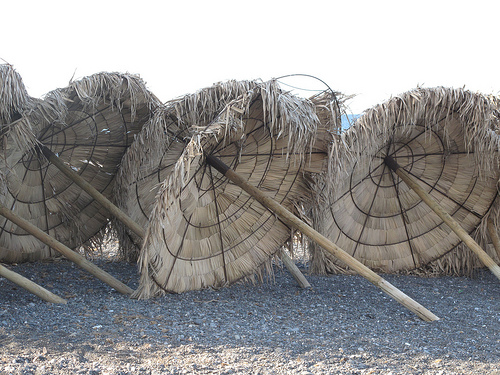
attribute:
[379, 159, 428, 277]
black support — on umbrella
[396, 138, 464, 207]
black support — on umbrella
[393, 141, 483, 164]
black support — on umbrella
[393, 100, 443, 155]
black support — on umbrella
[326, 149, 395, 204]
black support — on umbrella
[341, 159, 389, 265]
black support — on umbrella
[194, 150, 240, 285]
black support — on umbrella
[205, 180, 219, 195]
support — on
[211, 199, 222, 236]
support — on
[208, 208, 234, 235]
support — on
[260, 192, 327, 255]
pole — on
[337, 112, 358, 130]
water — behind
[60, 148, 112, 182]
holes — in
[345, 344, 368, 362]
rock — on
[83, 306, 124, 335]
dirt — on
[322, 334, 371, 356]
sand — on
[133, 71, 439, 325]
umbrella — beach umbrella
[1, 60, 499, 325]
umbrellas — hand made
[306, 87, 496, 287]
umbrella — beach umbrella